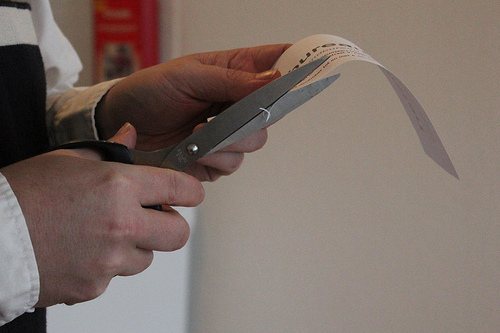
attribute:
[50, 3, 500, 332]
walls — white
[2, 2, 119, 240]
shirt — black, white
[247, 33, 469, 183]
paper — white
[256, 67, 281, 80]
fingernails — short